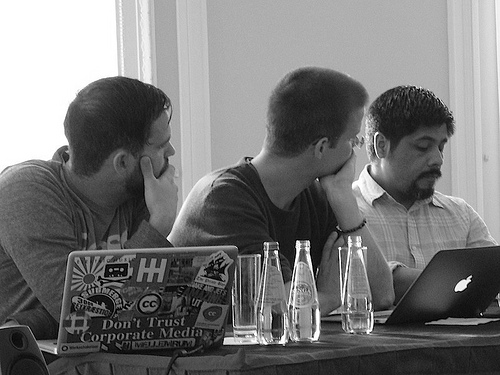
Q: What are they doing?
A: Sitting.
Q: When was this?
A: Daytime.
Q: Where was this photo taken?
A: At work.